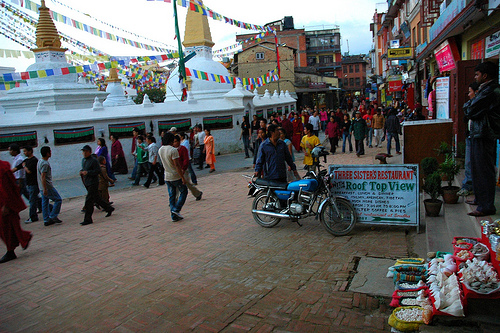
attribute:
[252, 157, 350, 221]
motorcyle — here, parked, blue, painted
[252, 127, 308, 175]
man — light, here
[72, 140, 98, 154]
cap — here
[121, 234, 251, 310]
ground — here, stoney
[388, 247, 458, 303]
bags — small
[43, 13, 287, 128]
building — tall, white, here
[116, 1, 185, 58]
sky — blue, here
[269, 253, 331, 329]
walkway — brick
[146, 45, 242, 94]
banners — colorful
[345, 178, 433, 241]
display — sale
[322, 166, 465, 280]
sign — advertising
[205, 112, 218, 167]
woman — wearing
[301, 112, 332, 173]
boy — wearing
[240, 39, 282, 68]
window — small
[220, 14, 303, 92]
buildings — multistory, brick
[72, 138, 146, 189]
men — walking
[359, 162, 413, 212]
poster — red, white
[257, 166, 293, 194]
seat — black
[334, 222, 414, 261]
floor — old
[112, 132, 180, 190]
people — here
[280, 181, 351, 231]
motorbike — parked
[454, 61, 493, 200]
people — standing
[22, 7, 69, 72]
steeple — yellow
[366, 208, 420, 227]
arrow — green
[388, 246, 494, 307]
items — grocery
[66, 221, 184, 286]
road — here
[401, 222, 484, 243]
staircase — here